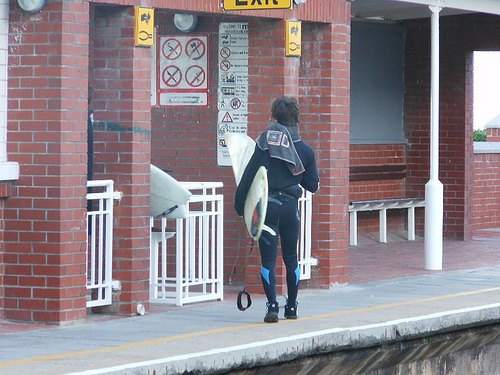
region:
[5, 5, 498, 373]
surfer with surfboard at transportation station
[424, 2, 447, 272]
white supporting pillar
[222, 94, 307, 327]
surfer in wetsuit with white surfboard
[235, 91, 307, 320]
surfer wearing black wetsuit with blue accents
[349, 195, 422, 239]
white seating bench at transit station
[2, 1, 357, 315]
brickwork doorways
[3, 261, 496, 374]
stone transit platform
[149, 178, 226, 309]
white transit gate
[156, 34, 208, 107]
placard showing prohibited items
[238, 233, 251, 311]
surfboard leash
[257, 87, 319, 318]
young man in full wet suit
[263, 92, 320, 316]
young man with towel on shoulder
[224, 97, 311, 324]
young person carrying short surfboard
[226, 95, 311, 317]
young person in black and blue wetsuit carrying white surfboard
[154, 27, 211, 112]
sign displaying actions not allowed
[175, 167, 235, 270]
white fencing against red brick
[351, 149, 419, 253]
white bench against red brick wall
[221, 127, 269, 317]
surfboard with leash hanging down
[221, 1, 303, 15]
bottom half of yellow exit sign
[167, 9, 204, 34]
bottom half of light on red brick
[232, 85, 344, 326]
this is a man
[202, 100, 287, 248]
this is a surf board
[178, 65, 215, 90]
this is a sign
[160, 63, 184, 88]
this is a sign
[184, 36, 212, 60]
this is a sign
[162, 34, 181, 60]
this is a sign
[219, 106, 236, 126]
this is a sign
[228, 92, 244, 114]
this is a sign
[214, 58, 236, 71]
this is a sign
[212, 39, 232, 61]
this is a sign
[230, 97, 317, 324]
the man in a wet suit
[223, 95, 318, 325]
the man carrying the surfboard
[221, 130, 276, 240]
the surfboard in the man's arm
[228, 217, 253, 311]
the chord on the surfboard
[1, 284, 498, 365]
the yellow line on the ground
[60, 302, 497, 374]
the white line on the ground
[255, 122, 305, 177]
the towel on the man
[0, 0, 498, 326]
the building made of bricks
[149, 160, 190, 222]
the end of the surfboard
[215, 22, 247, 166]
the sign on the wall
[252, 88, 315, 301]
this is a mam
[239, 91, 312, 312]
the man is standing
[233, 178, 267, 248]
he is carrying a surf board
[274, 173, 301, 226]
the costume is black in color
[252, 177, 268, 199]
the board is white in color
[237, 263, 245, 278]
this is a rope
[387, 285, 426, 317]
the pavement is tarmacked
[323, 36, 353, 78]
this is the wall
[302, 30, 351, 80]
the wall is made of bricks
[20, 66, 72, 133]
the wall is red in color